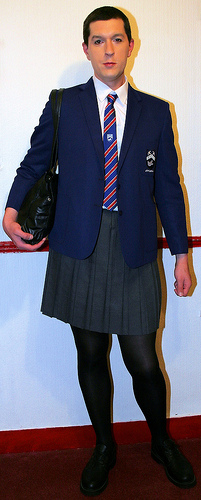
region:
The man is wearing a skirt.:
[58, 233, 162, 321]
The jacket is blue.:
[60, 159, 94, 196]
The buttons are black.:
[109, 180, 129, 215]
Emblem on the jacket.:
[138, 147, 160, 178]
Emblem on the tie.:
[103, 135, 118, 146]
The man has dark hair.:
[78, 6, 130, 37]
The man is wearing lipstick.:
[101, 56, 124, 67]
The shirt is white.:
[89, 82, 128, 101]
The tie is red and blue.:
[102, 154, 120, 179]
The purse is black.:
[24, 178, 57, 227]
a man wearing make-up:
[77, 5, 138, 84]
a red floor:
[9, 435, 70, 477]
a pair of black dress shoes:
[74, 428, 195, 495]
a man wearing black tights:
[60, 317, 178, 447]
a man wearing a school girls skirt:
[6, 5, 187, 358]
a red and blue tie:
[96, 89, 123, 212]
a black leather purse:
[15, 75, 58, 258]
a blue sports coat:
[9, 72, 189, 268]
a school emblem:
[140, 143, 160, 180]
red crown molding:
[1, 235, 48, 256]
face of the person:
[78, 10, 143, 75]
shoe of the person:
[71, 446, 106, 490]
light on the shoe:
[89, 481, 96, 489]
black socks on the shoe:
[93, 426, 109, 433]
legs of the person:
[75, 380, 181, 427]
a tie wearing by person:
[100, 93, 118, 215]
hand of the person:
[171, 245, 191, 300]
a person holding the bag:
[13, 174, 69, 254]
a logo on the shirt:
[143, 142, 162, 186]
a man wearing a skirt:
[1, 0, 197, 498]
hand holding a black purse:
[1, 149, 64, 259]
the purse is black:
[12, 166, 61, 243]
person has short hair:
[28, 0, 181, 144]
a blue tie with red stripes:
[99, 93, 124, 214]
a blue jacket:
[1, 77, 192, 265]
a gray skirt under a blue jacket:
[40, 200, 164, 338]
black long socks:
[71, 327, 192, 493]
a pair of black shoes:
[70, 436, 199, 498]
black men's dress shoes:
[74, 433, 195, 497]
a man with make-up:
[71, 5, 143, 84]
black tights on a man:
[56, 309, 178, 448]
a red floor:
[16, 438, 72, 480]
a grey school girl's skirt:
[39, 193, 170, 351]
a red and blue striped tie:
[95, 89, 126, 225]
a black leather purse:
[19, 77, 62, 249]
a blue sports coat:
[8, 66, 190, 273]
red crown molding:
[0, 237, 53, 254]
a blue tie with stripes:
[101, 89, 128, 214]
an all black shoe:
[143, 435, 198, 497]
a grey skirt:
[41, 210, 185, 348]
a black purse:
[9, 168, 68, 245]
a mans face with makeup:
[75, 8, 142, 89]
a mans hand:
[167, 248, 194, 301]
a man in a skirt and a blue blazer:
[2, 5, 195, 492]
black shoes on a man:
[79, 443, 117, 494]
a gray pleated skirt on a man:
[40, 207, 161, 333]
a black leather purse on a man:
[16, 85, 63, 244]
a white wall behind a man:
[0, 0, 200, 238]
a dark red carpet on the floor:
[0, 438, 200, 498]